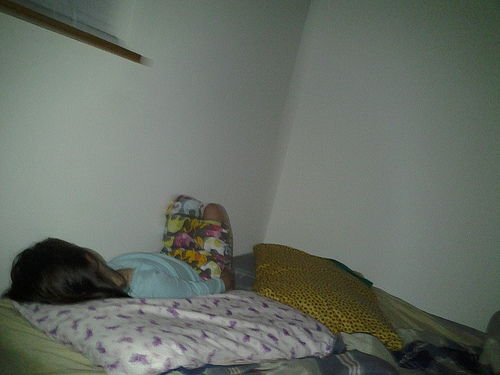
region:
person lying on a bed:
[8, 165, 336, 372]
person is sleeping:
[6, 182, 246, 324]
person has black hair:
[4, 225, 164, 325]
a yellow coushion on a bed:
[245, 231, 410, 355]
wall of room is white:
[268, 11, 493, 242]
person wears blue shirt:
[16, 179, 249, 312]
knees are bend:
[157, 187, 237, 237]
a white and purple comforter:
[38, 286, 354, 367]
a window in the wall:
[2, 4, 157, 89]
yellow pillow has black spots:
[245, 230, 408, 353]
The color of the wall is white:
[298, 58, 470, 228]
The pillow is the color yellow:
[255, 223, 413, 353]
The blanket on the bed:
[176, 338, 491, 373]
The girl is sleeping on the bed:
[9, 180, 262, 322]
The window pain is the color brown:
[1, 0, 145, 65]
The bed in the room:
[10, 233, 487, 370]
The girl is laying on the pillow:
[1, 228, 340, 370]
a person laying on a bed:
[13, 182, 268, 307]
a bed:
[8, 244, 404, 366]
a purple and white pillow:
[60, 296, 311, 373]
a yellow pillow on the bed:
[258, 238, 380, 331]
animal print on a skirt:
[166, 206, 239, 269]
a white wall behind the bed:
[293, 35, 467, 268]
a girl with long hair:
[3, 210, 246, 292]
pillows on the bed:
[88, 265, 443, 367]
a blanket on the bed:
[393, 303, 459, 370]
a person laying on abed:
[6, 188, 238, 308]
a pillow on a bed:
[249, 225, 399, 350]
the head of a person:
[1, 235, 132, 307]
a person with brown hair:
[1, 238, 124, 306]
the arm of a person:
[155, 269, 240, 299]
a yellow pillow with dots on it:
[255, 235, 388, 341]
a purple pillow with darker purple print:
[67, 296, 318, 372]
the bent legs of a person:
[161, 193, 241, 291]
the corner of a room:
[252, 0, 319, 243]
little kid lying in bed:
[16, 194, 238, 302]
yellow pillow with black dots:
[253, 237, 398, 347]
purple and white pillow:
[25, 294, 334, 369]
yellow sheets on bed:
[8, 269, 482, 372]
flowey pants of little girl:
[158, 197, 227, 285]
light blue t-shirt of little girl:
[104, 248, 224, 298]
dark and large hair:
[4, 237, 133, 304]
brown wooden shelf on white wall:
[0, 1, 147, 66]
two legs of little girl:
[158, 192, 235, 280]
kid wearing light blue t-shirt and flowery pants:
[5, 191, 234, 306]